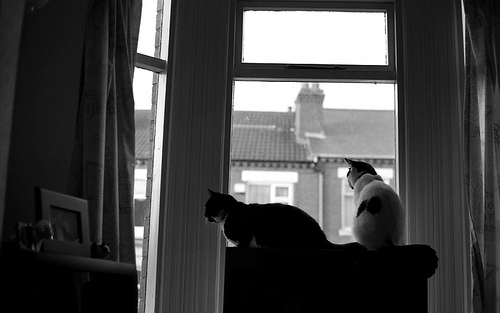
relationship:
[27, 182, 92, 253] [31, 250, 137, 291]
picture on shelf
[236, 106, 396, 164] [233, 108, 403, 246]
roof of house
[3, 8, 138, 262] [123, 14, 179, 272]
curtain for window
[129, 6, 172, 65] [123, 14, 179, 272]
top section of window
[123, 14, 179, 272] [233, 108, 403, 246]
window of house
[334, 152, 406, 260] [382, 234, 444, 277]
cat has tail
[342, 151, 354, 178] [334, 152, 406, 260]
ear on cat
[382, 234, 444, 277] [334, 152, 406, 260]
tail on cat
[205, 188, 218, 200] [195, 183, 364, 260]
ear on cat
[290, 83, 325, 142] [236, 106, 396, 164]
chimney on roof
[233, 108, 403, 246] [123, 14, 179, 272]
house out window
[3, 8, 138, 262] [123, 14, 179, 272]
curtain on window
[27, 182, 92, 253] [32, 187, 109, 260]
picture in frame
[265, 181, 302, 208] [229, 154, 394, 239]
window on building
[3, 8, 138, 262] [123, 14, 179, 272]
curtain by window